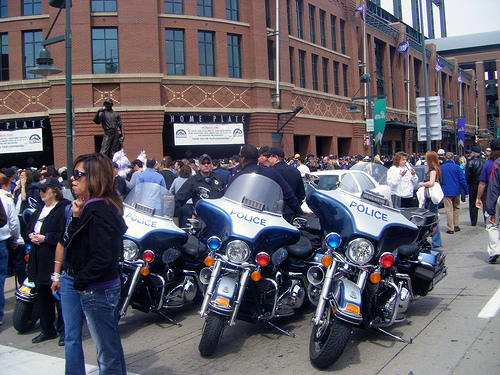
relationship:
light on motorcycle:
[326, 234, 341, 247] [304, 175, 449, 371]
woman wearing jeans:
[62, 151, 127, 374] [78, 283, 126, 375]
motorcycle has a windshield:
[304, 175, 449, 371] [338, 160, 403, 212]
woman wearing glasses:
[62, 151, 127, 374] [73, 169, 88, 179]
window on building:
[162, 25, 187, 77] [2, 1, 498, 170]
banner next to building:
[372, 95, 386, 148] [2, 1, 498, 170]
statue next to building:
[91, 98, 125, 160] [2, 1, 498, 170]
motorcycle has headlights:
[304, 175, 449, 371] [324, 232, 395, 269]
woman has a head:
[62, 151, 127, 374] [69, 155, 111, 199]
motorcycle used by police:
[194, 173, 325, 355] [167, 144, 304, 211]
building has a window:
[2, 1, 498, 170] [162, 25, 187, 77]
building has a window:
[2, 1, 498, 170] [196, 28, 217, 80]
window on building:
[225, 30, 244, 81] [2, 1, 498, 170]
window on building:
[196, 28, 217, 80] [2, 1, 498, 170]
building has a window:
[2, 1, 498, 170] [225, 30, 244, 81]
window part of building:
[162, 25, 187, 77] [2, 1, 498, 170]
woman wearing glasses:
[62, 151, 127, 374] [74, 169, 88, 179]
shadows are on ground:
[2, 285, 444, 375] [1, 194, 498, 373]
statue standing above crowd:
[91, 98, 125, 160] [1, 147, 499, 282]